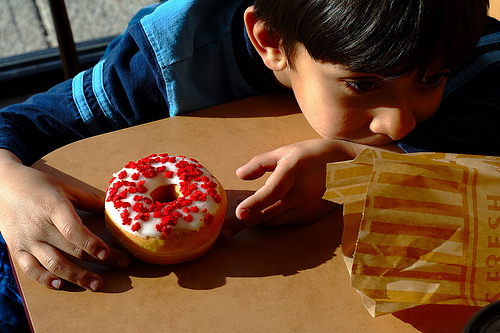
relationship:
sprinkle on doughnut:
[106, 147, 222, 227] [92, 150, 234, 265]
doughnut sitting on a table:
[92, 150, 234, 265] [2, 90, 497, 332]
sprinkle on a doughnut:
[103, 151, 221, 238] [90, 143, 237, 269]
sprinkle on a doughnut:
[103, 151, 221, 238] [106, 149, 223, 266]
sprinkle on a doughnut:
[103, 151, 221, 238] [92, 150, 234, 265]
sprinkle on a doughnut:
[103, 151, 221, 238] [96, 152, 221, 256]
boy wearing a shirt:
[6, 0, 496, 292] [63, 7, 209, 97]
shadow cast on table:
[232, 191, 346, 311] [56, 122, 379, 326]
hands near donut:
[16, 134, 338, 300] [102, 152, 227, 265]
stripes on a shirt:
[71, 59, 119, 127] [1, 17, 482, 283]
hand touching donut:
[24, 171, 124, 305] [87, 152, 236, 272]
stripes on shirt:
[56, 55, 98, 133] [51, 6, 278, 108]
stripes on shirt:
[71, 59, 119, 127] [51, 6, 278, 108]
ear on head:
[215, 12, 306, 77] [251, 4, 477, 161]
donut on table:
[104, 145, 231, 264] [207, 240, 293, 321]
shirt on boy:
[0, 0, 293, 161] [105, 7, 485, 165]